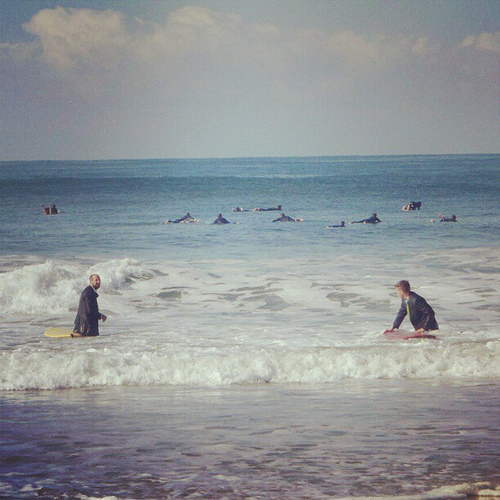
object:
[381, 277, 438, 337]
person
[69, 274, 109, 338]
person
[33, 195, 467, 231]
people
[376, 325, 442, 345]
board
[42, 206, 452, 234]
boards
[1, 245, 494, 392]
waves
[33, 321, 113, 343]
board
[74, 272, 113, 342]
surfer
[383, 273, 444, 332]
surfer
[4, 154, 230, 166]
line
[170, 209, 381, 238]
group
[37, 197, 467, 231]
surfers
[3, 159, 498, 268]
back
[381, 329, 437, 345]
surfboard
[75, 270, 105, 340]
man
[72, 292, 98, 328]
coat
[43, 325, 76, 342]
surfboard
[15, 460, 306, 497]
shore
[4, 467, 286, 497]
beach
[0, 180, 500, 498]
water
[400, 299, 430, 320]
jacket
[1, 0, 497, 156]
sky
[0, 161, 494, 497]
ocean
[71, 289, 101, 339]
suit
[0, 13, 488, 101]
clouds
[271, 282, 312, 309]
bubbles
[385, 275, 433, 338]
man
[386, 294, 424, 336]
tie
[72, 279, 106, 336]
jacket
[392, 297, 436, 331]
suit